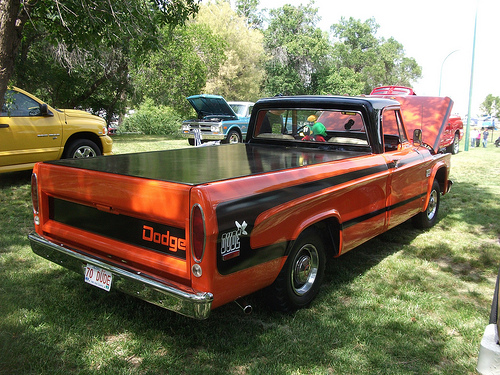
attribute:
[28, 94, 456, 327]
truck — sitting on the grass, parked, black, red pickup, red, a dodge pickup, in a show event, an older model, orange, parked on grass, vintage dodge pickup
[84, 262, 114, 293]
license plate — registered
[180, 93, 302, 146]
truck — sitting on the grass, blue dodge, on the grass, vintage pickup truck, parked, blue, white dodge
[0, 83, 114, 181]
truck — parked, gold dodge pickup, sitting on the grass, on the grass, parked on the grass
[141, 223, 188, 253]
dodge — written on the truck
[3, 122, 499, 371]
grass — under the truck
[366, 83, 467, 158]
truck — on the grass, sitting on the grass, parked